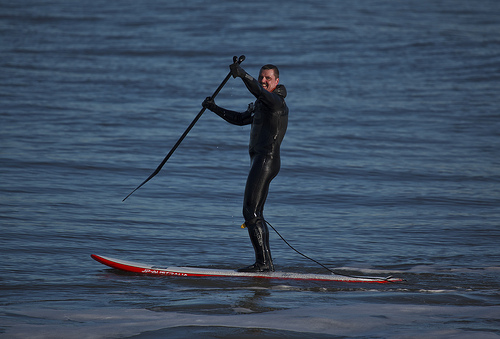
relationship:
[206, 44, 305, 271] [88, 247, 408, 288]
man on board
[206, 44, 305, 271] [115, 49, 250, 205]
man holding oar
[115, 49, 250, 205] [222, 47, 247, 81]
oar in hand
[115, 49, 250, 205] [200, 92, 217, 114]
oar in hand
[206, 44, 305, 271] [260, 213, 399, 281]
man holding wire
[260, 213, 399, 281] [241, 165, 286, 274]
wire between legs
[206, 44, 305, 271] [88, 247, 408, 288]
man on surfboard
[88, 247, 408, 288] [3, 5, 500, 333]
surfboard in water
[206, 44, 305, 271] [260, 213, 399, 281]
man wearing leg leash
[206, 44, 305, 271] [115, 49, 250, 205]
man holding pole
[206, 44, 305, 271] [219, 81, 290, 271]
man wearing wetsuit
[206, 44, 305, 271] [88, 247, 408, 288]
man on paddleboard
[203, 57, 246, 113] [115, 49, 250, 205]
hands on handle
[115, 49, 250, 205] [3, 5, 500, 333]
paddle above water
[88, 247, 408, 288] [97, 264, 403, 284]
board has red edge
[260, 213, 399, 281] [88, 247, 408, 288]
cord attached to board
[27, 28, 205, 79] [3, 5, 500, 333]
ripples on water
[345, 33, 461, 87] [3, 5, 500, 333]
ripples on water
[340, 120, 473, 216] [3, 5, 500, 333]
ripples on water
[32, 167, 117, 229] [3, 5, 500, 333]
ripples on water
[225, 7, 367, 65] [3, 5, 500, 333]
ripples on water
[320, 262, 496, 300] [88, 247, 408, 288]
ripple made by board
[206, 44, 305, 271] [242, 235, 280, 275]
man wearing booties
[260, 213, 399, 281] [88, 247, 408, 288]
rope connected to board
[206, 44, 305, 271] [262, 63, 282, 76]
man has hair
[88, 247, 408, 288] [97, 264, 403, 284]
board has edge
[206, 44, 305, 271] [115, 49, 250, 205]
man has pole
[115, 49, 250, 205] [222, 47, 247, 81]
pole in hand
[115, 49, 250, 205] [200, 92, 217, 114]
pole in hand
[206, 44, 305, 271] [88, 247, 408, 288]
man on surf board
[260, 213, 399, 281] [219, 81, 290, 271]
cord attached to wetsuit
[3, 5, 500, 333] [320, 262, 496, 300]
water has wave